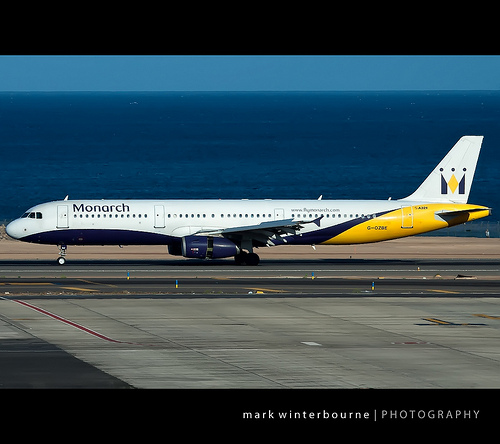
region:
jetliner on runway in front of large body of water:
[1, 92, 498, 279]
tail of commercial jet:
[402, 134, 484, 204]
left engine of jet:
[180, 234, 240, 260]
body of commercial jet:
[42, 197, 487, 244]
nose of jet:
[2, 202, 49, 244]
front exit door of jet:
[55, 204, 70, 230]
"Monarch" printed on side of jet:
[70, 199, 131, 214]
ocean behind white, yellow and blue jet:
[2, 90, 499, 235]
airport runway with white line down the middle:
[2, 261, 498, 278]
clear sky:
[0, 57, 499, 92]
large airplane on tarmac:
[8, 118, 490, 282]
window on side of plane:
[69, 210, 78, 222]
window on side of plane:
[79, 213, 88, 225]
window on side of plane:
[91, 210, 100, 219]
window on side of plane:
[101, 210, 105, 217]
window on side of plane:
[111, 210, 120, 223]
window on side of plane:
[208, 212, 222, 222]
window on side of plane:
[221, 211, 228, 221]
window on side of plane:
[238, 212, 242, 221]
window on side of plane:
[267, 210, 275, 220]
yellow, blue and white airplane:
[4, 137, 490, 262]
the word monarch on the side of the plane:
[71, 201, 131, 213]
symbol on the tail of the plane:
[436, 162, 467, 198]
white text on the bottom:
[239, 408, 483, 419]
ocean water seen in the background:
[0, 89, 499, 236]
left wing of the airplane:
[201, 217, 303, 241]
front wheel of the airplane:
[56, 242, 67, 269]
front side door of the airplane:
[53, 204, 71, 229]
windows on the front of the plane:
[19, 210, 44, 218]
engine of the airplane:
[164, 237, 237, 259]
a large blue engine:
[179, 235, 244, 262]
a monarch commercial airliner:
[7, 130, 492, 264]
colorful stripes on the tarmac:
[411, 305, 491, 330]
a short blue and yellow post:
[367, 279, 378, 291]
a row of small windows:
[166, 211, 276, 221]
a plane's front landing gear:
[53, 245, 73, 267]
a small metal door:
[55, 203, 75, 231]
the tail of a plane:
[413, 128, 491, 228]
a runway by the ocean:
[2, 168, 492, 290]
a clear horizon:
[11, 67, 468, 102]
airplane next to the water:
[170, 153, 241, 215]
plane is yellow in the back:
[399, 197, 448, 240]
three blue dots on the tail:
[438, 153, 472, 175]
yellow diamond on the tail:
[447, 172, 460, 197]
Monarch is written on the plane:
[77, 195, 135, 219]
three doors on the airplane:
[51, 206, 293, 219]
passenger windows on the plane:
[76, 207, 119, 218]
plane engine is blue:
[183, 235, 229, 257]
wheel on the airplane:
[41, 250, 83, 271]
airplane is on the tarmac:
[43, 234, 354, 284]